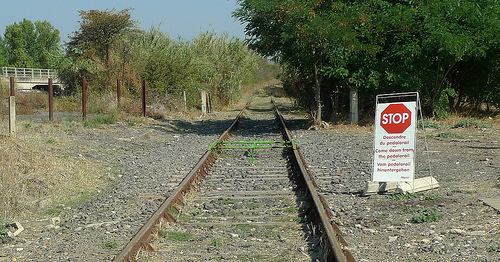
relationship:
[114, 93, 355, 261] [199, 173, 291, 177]
track has tie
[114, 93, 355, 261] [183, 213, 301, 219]
track has tie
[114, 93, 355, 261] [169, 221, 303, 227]
track has tie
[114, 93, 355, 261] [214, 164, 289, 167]
track has tie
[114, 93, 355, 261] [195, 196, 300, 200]
track has tie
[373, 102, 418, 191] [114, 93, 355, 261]
sign beside track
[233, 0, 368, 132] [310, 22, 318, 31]
tree has leaf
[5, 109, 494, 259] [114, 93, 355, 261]
gravel beside track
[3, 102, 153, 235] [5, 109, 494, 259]
grass beside gravel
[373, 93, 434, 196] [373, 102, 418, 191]
holder for sign